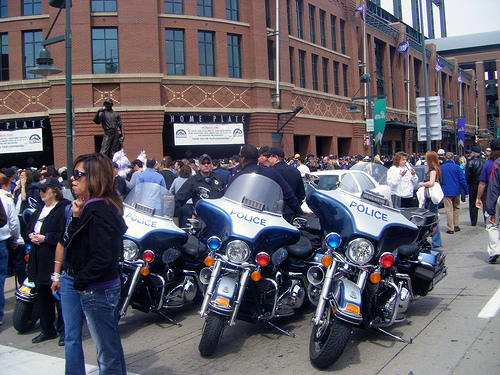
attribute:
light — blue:
[326, 234, 341, 247]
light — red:
[379, 253, 395, 269]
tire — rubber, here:
[308, 315, 354, 371]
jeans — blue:
[78, 283, 126, 375]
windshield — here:
[338, 160, 403, 212]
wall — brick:
[1, 0, 499, 165]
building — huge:
[2, 1, 498, 170]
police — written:
[348, 201, 388, 222]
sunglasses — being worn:
[71, 168, 90, 180]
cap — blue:
[33, 177, 62, 189]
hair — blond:
[424, 150, 443, 184]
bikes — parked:
[117, 173, 448, 365]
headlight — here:
[348, 237, 375, 265]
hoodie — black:
[61, 198, 128, 289]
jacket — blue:
[64, 198, 128, 290]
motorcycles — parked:
[118, 169, 450, 367]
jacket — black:
[26, 198, 65, 286]